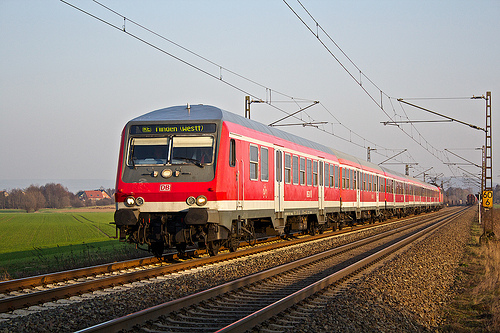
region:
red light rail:
[114, 96, 425, 233]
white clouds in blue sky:
[345, 56, 367, 83]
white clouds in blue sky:
[341, 56, 398, 78]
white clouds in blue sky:
[305, 13, 357, 61]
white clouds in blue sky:
[271, 35, 338, 76]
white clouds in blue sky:
[40, 30, 130, 66]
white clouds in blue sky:
[6, 55, 41, 88]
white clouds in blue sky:
[26, 105, 69, 152]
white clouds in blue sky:
[80, 15, 160, 62]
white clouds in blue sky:
[207, 22, 315, 76]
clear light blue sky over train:
[3, 5, 493, 185]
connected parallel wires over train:
[65, 1, 475, 187]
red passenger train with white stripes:
[110, 105, 440, 236]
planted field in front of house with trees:
[0, 180, 111, 275]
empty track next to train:
[85, 200, 475, 325]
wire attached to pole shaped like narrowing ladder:
[377, 80, 492, 230]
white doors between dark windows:
[265, 142, 440, 204]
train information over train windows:
[120, 115, 215, 165]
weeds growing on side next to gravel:
[310, 201, 495, 326]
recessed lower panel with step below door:
[270, 145, 286, 236]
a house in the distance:
[71, 177, 113, 218]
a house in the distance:
[80, 181, 113, 207]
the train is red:
[97, 76, 443, 242]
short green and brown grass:
[13, 217, 42, 235]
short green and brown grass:
[67, 220, 90, 236]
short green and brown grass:
[7, 221, 52, 250]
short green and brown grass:
[52, 225, 89, 246]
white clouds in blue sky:
[22, 39, 87, 85]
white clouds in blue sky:
[347, 45, 387, 85]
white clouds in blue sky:
[282, 40, 312, 55]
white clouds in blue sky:
[192, 17, 234, 70]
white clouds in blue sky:
[375, 42, 438, 78]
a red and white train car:
[110, 102, 337, 252]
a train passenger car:
[335, 148, 361, 228]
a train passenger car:
[361, 156, 385, 222]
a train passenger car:
[384, 165, 396, 219]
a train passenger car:
[398, 170, 407, 216]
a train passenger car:
[406, 175, 413, 214]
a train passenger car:
[414, 179, 421, 212]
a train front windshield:
[130, 136, 214, 166]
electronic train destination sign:
[133, 123, 214, 133]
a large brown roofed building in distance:
[80, 189, 110, 201]